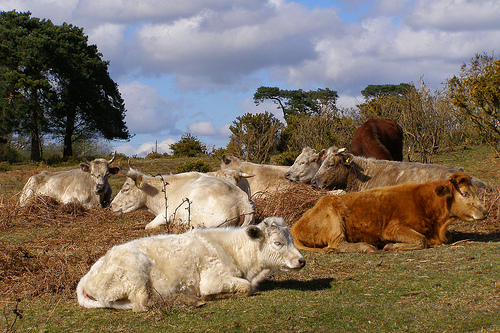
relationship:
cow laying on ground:
[72, 216, 307, 312] [2, 241, 497, 330]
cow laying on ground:
[290, 171, 489, 254] [2, 241, 497, 330]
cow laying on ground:
[109, 159, 255, 230] [2, 241, 497, 330]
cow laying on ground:
[19, 151, 119, 210] [2, 241, 497, 330]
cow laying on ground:
[311, 146, 498, 193] [2, 241, 497, 330]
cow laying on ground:
[19, 151, 119, 210] [0, 142, 498, 331]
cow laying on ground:
[109, 159, 255, 230] [0, 142, 498, 331]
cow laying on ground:
[290, 171, 489, 254] [0, 142, 498, 331]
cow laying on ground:
[76, 216, 306, 312] [0, 142, 498, 331]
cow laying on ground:
[311, 146, 487, 194] [0, 142, 498, 331]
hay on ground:
[5, 239, 75, 300] [2, 160, 496, 331]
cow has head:
[76, 216, 306, 312] [249, 225, 298, 277]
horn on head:
[108, 150, 119, 165] [76, 148, 121, 193]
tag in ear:
[246, 211, 262, 245] [242, 218, 274, 244]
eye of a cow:
[272, 240, 285, 249] [79, 221, 302, 308]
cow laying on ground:
[72, 216, 307, 312] [0, 142, 498, 331]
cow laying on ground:
[76, 216, 306, 312] [2, 160, 496, 331]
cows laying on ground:
[19, 118, 487, 313] [0, 142, 498, 331]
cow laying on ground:
[320, 181, 491, 244] [3, 152, 451, 331]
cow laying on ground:
[316, 146, 444, 184] [3, 152, 451, 331]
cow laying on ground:
[115, 171, 251, 221] [3, 152, 451, 331]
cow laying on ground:
[76, 216, 306, 312] [3, 152, 451, 331]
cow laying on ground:
[27, 159, 114, 199] [3, 152, 451, 331]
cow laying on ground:
[109, 159, 255, 230] [305, 263, 490, 328]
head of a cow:
[241, 212, 307, 275] [68, 211, 337, 327]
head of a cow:
[440, 169, 489, 228] [290, 171, 489, 254]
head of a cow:
[238, 204, 311, 273] [72, 216, 307, 312]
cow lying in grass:
[282, 143, 328, 180] [264, 244, 499, 331]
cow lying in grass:
[296, 142, 451, 187] [264, 244, 499, 331]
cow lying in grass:
[290, 171, 489, 254] [264, 244, 499, 331]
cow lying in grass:
[72, 216, 307, 312] [264, 244, 499, 331]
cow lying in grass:
[109, 159, 255, 230] [264, 244, 499, 331]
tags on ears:
[316, 147, 350, 164] [314, 145, 360, 168]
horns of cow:
[78, 149, 120, 165] [72, 216, 307, 312]